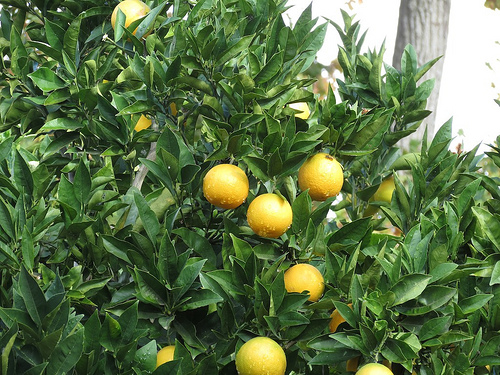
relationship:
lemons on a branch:
[102, 1, 422, 373] [123, 105, 161, 197]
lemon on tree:
[296, 149, 346, 201] [2, 1, 494, 370]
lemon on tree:
[246, 191, 292, 239] [2, 1, 494, 370]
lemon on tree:
[202, 160, 249, 207] [2, 1, 494, 370]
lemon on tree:
[278, 261, 325, 303] [2, 1, 494, 370]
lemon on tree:
[232, 332, 291, 374] [2, 1, 494, 370]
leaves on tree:
[399, 200, 481, 310] [27, 15, 486, 373]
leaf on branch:
[172, 255, 203, 293] [126, 13, 397, 340]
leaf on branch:
[225, 228, 252, 263] [126, 13, 397, 340]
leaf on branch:
[133, 190, 163, 245] [126, 13, 397, 340]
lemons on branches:
[201, 161, 253, 213] [2, 1, 162, 374]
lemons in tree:
[187, 147, 252, 200] [2, 1, 494, 370]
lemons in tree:
[229, 185, 316, 240] [2, 1, 494, 370]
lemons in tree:
[310, 151, 420, 248] [2, 1, 494, 370]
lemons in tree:
[229, 242, 450, 367] [2, 1, 494, 370]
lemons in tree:
[237, 317, 320, 372] [2, 1, 494, 370]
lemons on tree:
[173, 132, 408, 369] [2, 1, 494, 370]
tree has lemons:
[0, 132, 151, 375] [240, 192, 297, 248]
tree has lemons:
[2, 1, 494, 370] [143, 127, 435, 374]